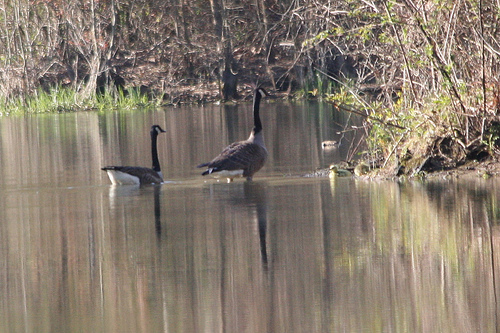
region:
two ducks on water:
[90, 91, 284, 195]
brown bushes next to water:
[365, 4, 483, 175]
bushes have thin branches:
[345, 11, 498, 150]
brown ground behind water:
[125, 0, 250, 95]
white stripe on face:
[254, 86, 269, 109]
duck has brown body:
[206, 126, 288, 165]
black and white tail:
[190, 161, 241, 180]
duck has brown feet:
[227, 168, 253, 190]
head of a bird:
[145, 117, 167, 134]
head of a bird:
[253, 83, 280, 102]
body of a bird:
[100, 154, 168, 193]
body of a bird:
[197, 132, 277, 183]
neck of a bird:
[150, 135, 164, 171]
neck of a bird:
[249, 100, 274, 140]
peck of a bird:
[159, 125, 170, 138]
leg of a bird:
[225, 176, 260, 191]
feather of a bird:
[190, 152, 225, 182]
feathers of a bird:
[94, 153, 134, 176]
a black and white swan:
[198, 85, 273, 185]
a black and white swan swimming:
[100, 120, 169, 189]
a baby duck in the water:
[323, 160, 352, 182]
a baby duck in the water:
[353, 158, 373, 177]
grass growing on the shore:
[6, 82, 163, 114]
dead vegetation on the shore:
[1, 0, 301, 92]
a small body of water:
[4, 101, 484, 331]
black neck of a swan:
[237, 81, 270, 132]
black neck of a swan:
[144, 129, 168, 173]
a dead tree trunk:
[204, 32, 247, 104]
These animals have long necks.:
[101, 84, 274, 196]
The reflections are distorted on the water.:
[110, 182, 280, 280]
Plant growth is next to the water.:
[299, 1, 497, 183]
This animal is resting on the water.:
[100, 123, 163, 186]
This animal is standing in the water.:
[200, 84, 276, 188]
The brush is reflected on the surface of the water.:
[340, 172, 497, 298]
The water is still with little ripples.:
[2, 104, 489, 329]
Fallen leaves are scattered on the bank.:
[117, 20, 324, 97]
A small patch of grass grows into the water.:
[7, 83, 167, 118]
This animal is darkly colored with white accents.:
[98, 120, 165, 197]